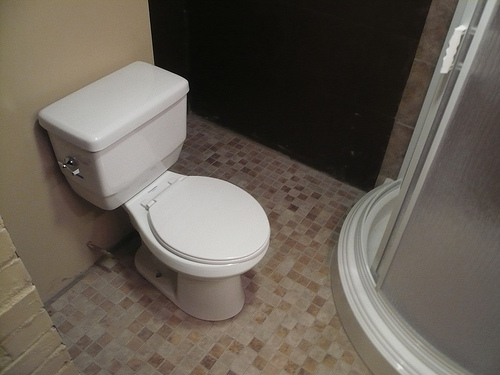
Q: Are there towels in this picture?
A: Yes, there is a towel.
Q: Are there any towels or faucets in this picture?
A: Yes, there is a towel.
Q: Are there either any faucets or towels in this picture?
A: Yes, there is a towel.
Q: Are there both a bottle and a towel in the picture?
A: No, there is a towel but no bottles.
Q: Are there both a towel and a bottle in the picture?
A: No, there is a towel but no bottles.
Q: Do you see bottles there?
A: No, there are no bottles.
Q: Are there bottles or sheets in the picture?
A: No, there are no bottles or sheets.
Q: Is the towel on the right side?
A: Yes, the towel is on the right of the image.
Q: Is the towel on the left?
A: No, the towel is on the right of the image.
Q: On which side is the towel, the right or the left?
A: The towel is on the right of the image.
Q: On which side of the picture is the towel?
A: The towel is on the right of the image.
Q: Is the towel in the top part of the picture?
A: Yes, the towel is in the top of the image.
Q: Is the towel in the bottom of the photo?
A: No, the towel is in the top of the image.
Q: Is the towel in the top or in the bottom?
A: The towel is in the top of the image.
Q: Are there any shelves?
A: No, there are no shelves.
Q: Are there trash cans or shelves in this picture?
A: No, there are no shelves or trash cans.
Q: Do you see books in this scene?
A: No, there are no books.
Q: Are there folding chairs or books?
A: No, there are no books or folding chairs.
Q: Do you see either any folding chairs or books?
A: No, there are no books or folding chairs.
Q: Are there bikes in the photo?
A: No, there are no bikes.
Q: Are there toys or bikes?
A: No, there are no bikes or toys.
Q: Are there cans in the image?
A: No, there are no cans.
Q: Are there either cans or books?
A: No, there are no cans or books.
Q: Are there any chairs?
A: No, there are no chairs.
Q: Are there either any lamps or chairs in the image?
A: No, there are no chairs or lamps.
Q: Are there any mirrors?
A: No, there are no mirrors.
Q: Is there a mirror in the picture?
A: No, there are no mirrors.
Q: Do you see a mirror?
A: No, there are no mirrors.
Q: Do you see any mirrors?
A: No, there are no mirrors.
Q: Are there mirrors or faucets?
A: No, there are no mirrors or faucets.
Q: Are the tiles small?
A: Yes, the tiles are small.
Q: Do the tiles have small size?
A: Yes, the tiles are small.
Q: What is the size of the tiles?
A: The tiles are small.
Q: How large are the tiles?
A: The tiles are small.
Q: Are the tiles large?
A: No, the tiles are small.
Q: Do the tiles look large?
A: No, the tiles are small.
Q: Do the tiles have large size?
A: No, the tiles are small.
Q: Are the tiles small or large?
A: The tiles are small.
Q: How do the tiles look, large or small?
A: The tiles are small.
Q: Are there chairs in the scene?
A: No, there are no chairs.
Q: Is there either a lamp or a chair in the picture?
A: No, there are no chairs or lamps.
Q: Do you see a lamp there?
A: No, there are no lamps.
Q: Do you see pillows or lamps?
A: No, there are no lamps or pillows.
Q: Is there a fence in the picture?
A: No, there are no fences.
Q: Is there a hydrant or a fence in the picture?
A: No, there are no fences or fire hydrants.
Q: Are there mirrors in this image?
A: No, there are no mirrors.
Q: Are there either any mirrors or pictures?
A: No, there are no mirrors or pictures.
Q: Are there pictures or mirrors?
A: No, there are no mirrors or pictures.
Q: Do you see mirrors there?
A: No, there are no mirrors.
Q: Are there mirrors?
A: No, there are no mirrors.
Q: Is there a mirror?
A: No, there are no mirrors.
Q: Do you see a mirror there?
A: No, there are no mirrors.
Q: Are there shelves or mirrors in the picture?
A: No, there are no mirrors or shelves.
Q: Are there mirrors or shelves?
A: No, there are no mirrors or shelves.